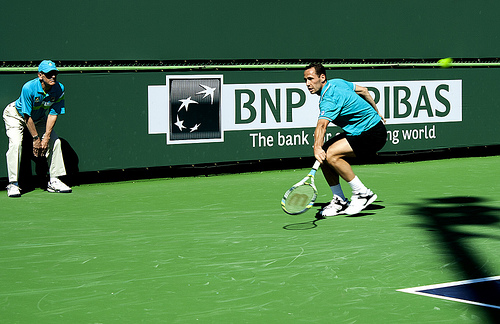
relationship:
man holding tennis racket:
[301, 63, 389, 216] [283, 152, 323, 217]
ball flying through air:
[429, 41, 459, 66] [289, 7, 497, 141]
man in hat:
[3, 50, 81, 200] [30, 56, 57, 79]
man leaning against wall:
[3, 50, 81, 200] [4, 60, 496, 182]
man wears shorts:
[209, 41, 404, 243] [336, 112, 419, 158]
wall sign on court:
[139, 68, 470, 151] [0, 153, 499, 323]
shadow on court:
[393, 181, 498, 321] [0, 153, 499, 323]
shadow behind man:
[393, 181, 498, 321] [301, 63, 389, 216]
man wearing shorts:
[301, 63, 389, 216] [323, 121, 386, 157]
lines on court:
[395, 283, 422, 296] [469, 282, 498, 301]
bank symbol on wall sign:
[165, 69, 225, 143] [144, 73, 462, 146]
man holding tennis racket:
[301, 63, 389, 216] [263, 144, 335, 215]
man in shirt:
[301, 63, 389, 216] [311, 76, 383, 136]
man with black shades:
[301, 63, 389, 216] [42, 69, 60, 79]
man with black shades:
[0, 59, 74, 197] [42, 69, 60, 79]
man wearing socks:
[301, 63, 389, 216] [323, 175, 371, 195]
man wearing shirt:
[301, 63, 389, 216] [316, 76, 381, 135]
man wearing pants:
[0, 59, 74, 197] [2, 100, 69, 181]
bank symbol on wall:
[164, 73, 226, 145] [1, 2, 498, 187]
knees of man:
[320, 144, 344, 164] [301, 63, 389, 216]